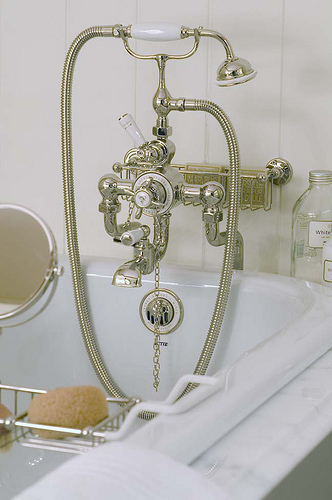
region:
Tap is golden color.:
[81, 174, 233, 290]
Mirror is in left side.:
[4, 209, 47, 327]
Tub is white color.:
[160, 394, 251, 460]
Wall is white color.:
[259, 33, 315, 143]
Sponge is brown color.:
[34, 382, 107, 437]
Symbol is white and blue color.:
[138, 288, 184, 343]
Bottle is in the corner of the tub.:
[289, 169, 331, 279]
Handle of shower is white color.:
[130, 17, 190, 43]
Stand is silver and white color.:
[12, 374, 150, 444]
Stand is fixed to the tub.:
[0, 370, 194, 453]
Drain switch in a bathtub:
[140, 286, 184, 334]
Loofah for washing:
[23, 384, 115, 446]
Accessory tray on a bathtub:
[0, 366, 228, 455]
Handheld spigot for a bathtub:
[46, 18, 261, 89]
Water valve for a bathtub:
[126, 171, 178, 219]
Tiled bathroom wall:
[258, 24, 304, 140]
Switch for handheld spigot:
[118, 224, 158, 256]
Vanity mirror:
[0, 199, 71, 331]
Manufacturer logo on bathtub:
[150, 337, 168, 346]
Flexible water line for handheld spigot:
[52, 85, 83, 205]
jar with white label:
[284, 167, 329, 274]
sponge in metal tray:
[18, 381, 111, 446]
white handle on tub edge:
[149, 371, 223, 421]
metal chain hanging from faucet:
[139, 245, 171, 393]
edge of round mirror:
[18, 204, 60, 303]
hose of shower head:
[49, 65, 87, 190]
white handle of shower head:
[127, 15, 190, 44]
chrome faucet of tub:
[110, 256, 150, 293]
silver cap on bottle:
[301, 166, 329, 191]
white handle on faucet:
[118, 223, 148, 255]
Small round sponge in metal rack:
[30, 374, 112, 432]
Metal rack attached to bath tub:
[0, 372, 227, 445]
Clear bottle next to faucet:
[286, 167, 330, 282]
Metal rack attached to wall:
[117, 156, 290, 212]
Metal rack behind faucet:
[115, 150, 292, 215]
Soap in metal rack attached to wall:
[227, 159, 273, 207]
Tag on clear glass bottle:
[304, 217, 330, 249]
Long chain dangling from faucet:
[151, 217, 160, 393]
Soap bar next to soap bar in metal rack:
[184, 156, 226, 203]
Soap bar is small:
[181, 159, 225, 200]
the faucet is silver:
[67, 216, 156, 304]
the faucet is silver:
[82, 178, 224, 382]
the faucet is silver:
[94, 215, 197, 355]